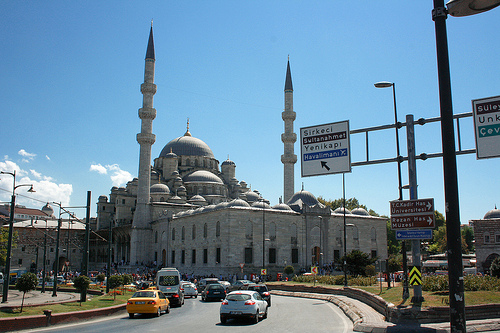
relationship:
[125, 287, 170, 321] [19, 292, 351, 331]
cab on road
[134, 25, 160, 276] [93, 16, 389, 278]
tower on building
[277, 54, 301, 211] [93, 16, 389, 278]
tower on building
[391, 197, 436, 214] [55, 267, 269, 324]
sign directing traffic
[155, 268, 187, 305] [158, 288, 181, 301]
bus with break lights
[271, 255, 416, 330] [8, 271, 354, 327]
walkway next to road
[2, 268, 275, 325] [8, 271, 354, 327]
vehicles on road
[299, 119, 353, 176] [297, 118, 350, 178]
sign on wall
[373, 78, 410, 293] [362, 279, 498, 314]
light on grass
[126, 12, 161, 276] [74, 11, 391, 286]
tower on building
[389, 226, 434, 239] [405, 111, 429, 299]
sign on pole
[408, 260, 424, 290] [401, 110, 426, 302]
sign on pole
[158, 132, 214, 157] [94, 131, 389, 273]
dome on building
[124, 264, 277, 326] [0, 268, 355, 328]
cars on street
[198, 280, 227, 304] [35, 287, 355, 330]
car driving on road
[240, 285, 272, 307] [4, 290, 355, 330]
car driving on road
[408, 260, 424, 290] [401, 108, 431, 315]
sign on pole